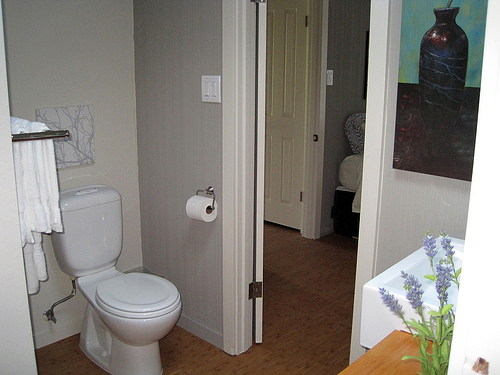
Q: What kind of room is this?
A: Bathroom.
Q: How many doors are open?
A: One.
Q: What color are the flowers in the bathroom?
A: Lavender.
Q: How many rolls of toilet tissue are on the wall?
A: One.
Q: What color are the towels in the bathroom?
A: White.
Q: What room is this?
A: Bathroom.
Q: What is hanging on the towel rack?
A: Towels.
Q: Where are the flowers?
A: On the counter next to the sink.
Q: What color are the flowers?
A: Purple.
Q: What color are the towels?
A: White.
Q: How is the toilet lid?
A: Down.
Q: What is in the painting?
A: A vase.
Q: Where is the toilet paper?
A: On the wall.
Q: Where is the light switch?
A: Above the toilet paper.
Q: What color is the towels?
A: White.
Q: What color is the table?
A: Brown.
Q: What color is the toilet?
A: White.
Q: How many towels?
A: Two.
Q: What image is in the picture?
A: Vase.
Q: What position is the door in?
A: Open.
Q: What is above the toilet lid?
A: Toilet tank.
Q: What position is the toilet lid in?
A: Closed.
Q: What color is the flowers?
A: Purple.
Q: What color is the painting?
A: Black and green.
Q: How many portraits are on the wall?
A: 1.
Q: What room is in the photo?
A: Bathroom.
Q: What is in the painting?
A: A vase.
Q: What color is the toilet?
A: White.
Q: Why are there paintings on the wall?
A: Decorations.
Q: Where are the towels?
A: On the towel rack.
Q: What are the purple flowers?
A: A Lavender plant.